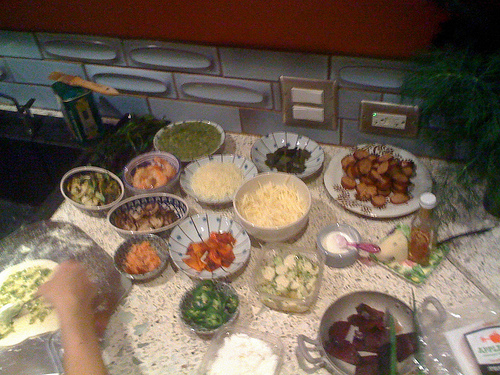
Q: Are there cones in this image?
A: No, there are no cones.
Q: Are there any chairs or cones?
A: No, there are no cones or chairs.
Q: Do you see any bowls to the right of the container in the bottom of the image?
A: Yes, there is a bowl to the right of the container.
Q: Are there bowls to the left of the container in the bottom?
A: No, the bowl is to the right of the container.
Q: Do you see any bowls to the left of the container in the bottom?
A: No, the bowl is to the right of the container.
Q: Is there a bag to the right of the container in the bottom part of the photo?
A: No, there is a bowl to the right of the container.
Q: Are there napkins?
A: No, there are no napkins.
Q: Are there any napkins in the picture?
A: No, there are no napkins.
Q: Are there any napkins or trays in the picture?
A: No, there are no napkins or trays.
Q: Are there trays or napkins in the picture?
A: No, there are no napkins or trays.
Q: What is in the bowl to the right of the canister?
A: The sauce is in the bowl.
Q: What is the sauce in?
A: The sauce is in the bowl.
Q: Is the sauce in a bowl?
A: Yes, the sauce is in a bowl.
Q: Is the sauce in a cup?
A: No, the sauce is in a bowl.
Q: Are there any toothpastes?
A: No, there are no toothpastes.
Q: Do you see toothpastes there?
A: No, there are no toothpastes.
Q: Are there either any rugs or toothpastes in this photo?
A: No, there are no toothpastes or rugs.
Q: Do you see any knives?
A: No, there are no knives.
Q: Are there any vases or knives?
A: No, there are no knives or vases.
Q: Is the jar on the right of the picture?
A: Yes, the jar is on the right of the image.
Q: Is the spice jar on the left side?
A: No, the jar is on the right of the image.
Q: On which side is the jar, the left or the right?
A: The jar is on the right of the image.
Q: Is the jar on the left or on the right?
A: The jar is on the right of the image.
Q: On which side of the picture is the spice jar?
A: The jar is on the right of the image.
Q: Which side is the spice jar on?
A: The jar is on the right of the image.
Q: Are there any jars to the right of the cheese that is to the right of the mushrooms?
A: Yes, there is a jar to the right of the cheese.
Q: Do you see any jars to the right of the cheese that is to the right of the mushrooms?
A: Yes, there is a jar to the right of the cheese.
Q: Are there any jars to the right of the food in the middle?
A: Yes, there is a jar to the right of the cheese.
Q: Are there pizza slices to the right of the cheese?
A: No, there is a jar to the right of the cheese.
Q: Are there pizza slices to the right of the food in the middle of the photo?
A: No, there is a jar to the right of the cheese.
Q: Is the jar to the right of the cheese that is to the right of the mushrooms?
A: Yes, the jar is to the right of the cheese.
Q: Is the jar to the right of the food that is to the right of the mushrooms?
A: Yes, the jar is to the right of the cheese.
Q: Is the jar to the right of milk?
A: No, the jar is to the right of the cheese.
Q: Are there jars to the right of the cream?
A: Yes, there is a jar to the right of the cream.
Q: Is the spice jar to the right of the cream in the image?
A: Yes, the jar is to the right of the cream.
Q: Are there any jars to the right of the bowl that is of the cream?
A: Yes, there is a jar to the right of the bowl.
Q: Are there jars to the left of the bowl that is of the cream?
A: No, the jar is to the right of the bowl.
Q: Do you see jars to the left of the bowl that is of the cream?
A: No, the jar is to the right of the bowl.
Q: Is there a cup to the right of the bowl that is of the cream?
A: No, there is a jar to the right of the bowl.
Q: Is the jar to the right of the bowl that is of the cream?
A: Yes, the jar is to the right of the bowl.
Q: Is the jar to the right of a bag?
A: No, the jar is to the right of the bowl.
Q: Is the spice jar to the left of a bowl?
A: No, the jar is to the right of a bowl.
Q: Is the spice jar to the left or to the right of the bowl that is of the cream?
A: The jar is to the right of the bowl.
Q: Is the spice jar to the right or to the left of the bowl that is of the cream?
A: The jar is to the right of the bowl.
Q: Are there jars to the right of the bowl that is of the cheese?
A: Yes, there is a jar to the right of the bowl.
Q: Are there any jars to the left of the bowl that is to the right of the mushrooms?
A: No, the jar is to the right of the bowl.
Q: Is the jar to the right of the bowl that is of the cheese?
A: Yes, the jar is to the right of the bowl.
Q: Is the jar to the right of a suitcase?
A: No, the jar is to the right of the bowl.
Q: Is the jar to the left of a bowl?
A: No, the jar is to the right of a bowl.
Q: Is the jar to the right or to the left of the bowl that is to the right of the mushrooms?
A: The jar is to the right of the bowl.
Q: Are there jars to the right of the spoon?
A: Yes, there is a jar to the right of the spoon.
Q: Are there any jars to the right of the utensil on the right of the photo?
A: Yes, there is a jar to the right of the spoon.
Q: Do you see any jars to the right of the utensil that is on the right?
A: Yes, there is a jar to the right of the spoon.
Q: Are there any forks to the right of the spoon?
A: No, there is a jar to the right of the spoon.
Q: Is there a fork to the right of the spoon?
A: No, there is a jar to the right of the spoon.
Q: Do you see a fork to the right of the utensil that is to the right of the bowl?
A: No, there is a jar to the right of the spoon.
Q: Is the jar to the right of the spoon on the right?
A: Yes, the jar is to the right of the spoon.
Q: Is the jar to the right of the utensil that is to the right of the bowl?
A: Yes, the jar is to the right of the spoon.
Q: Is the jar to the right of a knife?
A: No, the jar is to the right of the spoon.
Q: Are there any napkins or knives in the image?
A: No, there are no napkins or knives.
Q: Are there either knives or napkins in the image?
A: No, there are no napkins or knives.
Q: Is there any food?
A: Yes, there is food.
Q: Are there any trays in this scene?
A: No, there are no trays.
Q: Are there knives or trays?
A: No, there are no trays or knives.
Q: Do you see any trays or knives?
A: No, there are no trays or knives.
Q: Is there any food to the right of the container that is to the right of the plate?
A: Yes, there is food to the right of the container.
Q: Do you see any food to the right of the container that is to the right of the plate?
A: Yes, there is food to the right of the container.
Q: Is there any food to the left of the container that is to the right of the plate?
A: No, the food is to the right of the container.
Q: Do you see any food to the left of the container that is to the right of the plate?
A: No, the food is to the right of the container.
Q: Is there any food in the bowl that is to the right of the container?
A: Yes, there is food in the bowl.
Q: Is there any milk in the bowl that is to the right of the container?
A: No, there is food in the bowl.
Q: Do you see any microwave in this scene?
A: No, there are no microwaves.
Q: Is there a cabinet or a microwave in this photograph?
A: No, there are no microwaves or cabinets.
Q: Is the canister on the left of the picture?
A: Yes, the canister is on the left of the image.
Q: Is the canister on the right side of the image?
A: No, the canister is on the left of the image.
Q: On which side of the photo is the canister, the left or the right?
A: The canister is on the left of the image.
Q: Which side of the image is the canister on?
A: The canister is on the left of the image.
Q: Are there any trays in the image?
A: No, there are no trays.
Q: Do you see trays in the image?
A: No, there are no trays.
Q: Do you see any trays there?
A: No, there are no trays.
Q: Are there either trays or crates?
A: No, there are no trays or crates.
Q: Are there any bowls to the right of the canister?
A: Yes, there is a bowl to the right of the canister.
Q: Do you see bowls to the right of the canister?
A: Yes, there is a bowl to the right of the canister.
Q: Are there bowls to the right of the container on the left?
A: Yes, there is a bowl to the right of the canister.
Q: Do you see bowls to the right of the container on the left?
A: Yes, there is a bowl to the right of the canister.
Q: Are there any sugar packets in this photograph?
A: No, there are no sugar packets.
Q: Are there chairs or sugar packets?
A: No, there are no sugar packets or chairs.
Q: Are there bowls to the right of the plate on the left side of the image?
A: Yes, there is a bowl to the right of the plate.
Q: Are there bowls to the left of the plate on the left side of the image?
A: No, the bowl is to the right of the plate.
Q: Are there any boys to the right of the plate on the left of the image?
A: No, there is a bowl to the right of the plate.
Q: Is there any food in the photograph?
A: Yes, there is food.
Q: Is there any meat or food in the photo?
A: Yes, there is food.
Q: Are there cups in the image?
A: No, there are no cups.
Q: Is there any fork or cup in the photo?
A: No, there are no cups or forks.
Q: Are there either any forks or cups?
A: No, there are no cups or forks.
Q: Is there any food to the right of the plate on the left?
A: Yes, there is food to the right of the plate.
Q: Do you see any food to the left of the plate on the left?
A: No, the food is to the right of the plate.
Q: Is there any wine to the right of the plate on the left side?
A: No, there is food to the right of the plate.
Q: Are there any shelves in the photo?
A: No, there are no shelves.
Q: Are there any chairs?
A: No, there are no chairs.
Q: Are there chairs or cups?
A: No, there are no chairs or cups.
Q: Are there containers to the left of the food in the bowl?
A: Yes, there is a container to the left of the food.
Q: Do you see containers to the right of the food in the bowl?
A: No, the container is to the left of the food.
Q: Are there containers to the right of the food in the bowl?
A: No, the container is to the left of the food.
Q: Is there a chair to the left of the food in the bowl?
A: No, there is a container to the left of the food.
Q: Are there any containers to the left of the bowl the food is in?
A: Yes, there is a container to the left of the bowl.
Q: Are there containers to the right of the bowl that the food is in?
A: No, the container is to the left of the bowl.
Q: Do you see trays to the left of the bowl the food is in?
A: No, there is a container to the left of the bowl.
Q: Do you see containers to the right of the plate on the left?
A: Yes, there is a container to the right of the plate.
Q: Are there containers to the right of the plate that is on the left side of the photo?
A: Yes, there is a container to the right of the plate.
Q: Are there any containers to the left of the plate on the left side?
A: No, the container is to the right of the plate.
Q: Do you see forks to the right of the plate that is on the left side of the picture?
A: No, there is a container to the right of the plate.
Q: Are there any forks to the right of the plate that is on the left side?
A: No, there is a container to the right of the plate.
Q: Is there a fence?
A: No, there are no fences.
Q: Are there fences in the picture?
A: No, there are no fences.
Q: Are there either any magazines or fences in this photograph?
A: No, there are no fences or magazines.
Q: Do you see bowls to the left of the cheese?
A: Yes, there is a bowl to the left of the cheese.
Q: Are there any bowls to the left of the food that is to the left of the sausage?
A: Yes, there is a bowl to the left of the cheese.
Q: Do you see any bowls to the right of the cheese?
A: No, the bowl is to the left of the cheese.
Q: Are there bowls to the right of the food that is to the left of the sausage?
A: No, the bowl is to the left of the cheese.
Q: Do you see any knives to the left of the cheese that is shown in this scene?
A: No, there is a bowl to the left of the cheese.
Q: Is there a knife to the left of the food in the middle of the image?
A: No, there is a bowl to the left of the cheese.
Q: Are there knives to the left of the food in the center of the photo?
A: No, there is a bowl to the left of the cheese.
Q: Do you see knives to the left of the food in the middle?
A: No, there is a bowl to the left of the cheese.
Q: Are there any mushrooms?
A: Yes, there are mushrooms.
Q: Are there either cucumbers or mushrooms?
A: Yes, there are mushrooms.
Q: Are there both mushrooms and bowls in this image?
A: Yes, there are both mushrooms and a bowl.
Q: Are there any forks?
A: No, there are no forks.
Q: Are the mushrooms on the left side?
A: Yes, the mushrooms are on the left of the image.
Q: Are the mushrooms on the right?
A: No, the mushrooms are on the left of the image.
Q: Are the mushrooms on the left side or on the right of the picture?
A: The mushrooms are on the left of the image.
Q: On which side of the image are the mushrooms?
A: The mushrooms are on the left of the image.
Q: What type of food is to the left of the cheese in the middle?
A: The food is mushrooms.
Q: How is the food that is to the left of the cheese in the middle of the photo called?
A: The food is mushrooms.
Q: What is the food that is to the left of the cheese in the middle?
A: The food is mushrooms.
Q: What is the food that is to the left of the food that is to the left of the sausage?
A: The food is mushrooms.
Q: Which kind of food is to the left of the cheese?
A: The food is mushrooms.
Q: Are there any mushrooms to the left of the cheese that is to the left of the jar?
A: Yes, there are mushrooms to the left of the cheese.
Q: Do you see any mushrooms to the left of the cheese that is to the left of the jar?
A: Yes, there are mushrooms to the left of the cheese.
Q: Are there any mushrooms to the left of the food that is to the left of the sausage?
A: Yes, there are mushrooms to the left of the cheese.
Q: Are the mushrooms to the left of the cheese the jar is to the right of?
A: Yes, the mushrooms are to the left of the cheese.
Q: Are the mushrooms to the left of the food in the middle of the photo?
A: Yes, the mushrooms are to the left of the cheese.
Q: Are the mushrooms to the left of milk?
A: No, the mushrooms are to the left of the cheese.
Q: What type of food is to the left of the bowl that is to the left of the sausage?
A: The food is mushrooms.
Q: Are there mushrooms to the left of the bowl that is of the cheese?
A: Yes, there are mushrooms to the left of the bowl.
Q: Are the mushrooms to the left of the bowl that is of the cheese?
A: Yes, the mushrooms are to the left of the bowl.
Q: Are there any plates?
A: Yes, there is a plate.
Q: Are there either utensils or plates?
A: Yes, there is a plate.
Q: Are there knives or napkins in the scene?
A: No, there are no napkins or knives.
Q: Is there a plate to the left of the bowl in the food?
A: Yes, there is a plate to the left of the bowl.